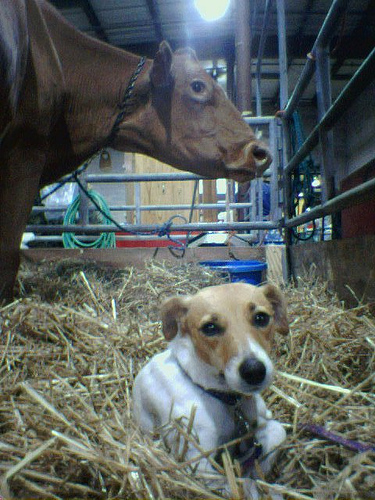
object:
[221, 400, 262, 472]
leash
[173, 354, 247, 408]
collar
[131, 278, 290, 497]
animal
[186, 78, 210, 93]
cow eye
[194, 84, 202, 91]
black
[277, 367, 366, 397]
hay stick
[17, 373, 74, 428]
hay stick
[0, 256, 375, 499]
hay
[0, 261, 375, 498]
stack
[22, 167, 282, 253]
railing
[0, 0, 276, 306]
cow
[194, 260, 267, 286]
bucket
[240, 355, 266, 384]
nose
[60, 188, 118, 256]
hose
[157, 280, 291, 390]
head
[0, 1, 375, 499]
pen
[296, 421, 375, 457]
leash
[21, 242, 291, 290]
pen